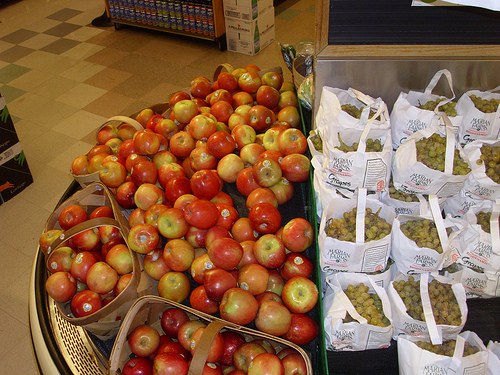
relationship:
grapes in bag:
[324, 207, 391, 243] [324, 193, 398, 257]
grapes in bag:
[348, 285, 376, 324] [322, 272, 395, 342]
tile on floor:
[96, 63, 119, 90] [1, 2, 316, 374]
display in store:
[32, 61, 498, 372] [13, 8, 494, 373]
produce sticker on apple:
[79, 300, 93, 312] [70, 288, 104, 319]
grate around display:
[47, 296, 107, 373] [62, 252, 306, 372]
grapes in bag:
[342, 282, 391, 327] [396, 330, 488, 373]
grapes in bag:
[413, 339, 483, 357] [321, 271, 393, 351]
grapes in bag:
[324, 207, 391, 243] [388, 271, 469, 340]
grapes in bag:
[400, 219, 452, 253] [317, 188, 395, 273]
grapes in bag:
[393, 274, 462, 324] [389, 193, 461, 275]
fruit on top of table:
[254, 156, 282, 188] [27, 175, 117, 372]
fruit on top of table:
[228, 86, 253, 107] [27, 175, 117, 372]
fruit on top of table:
[252, 232, 286, 270] [27, 175, 117, 372]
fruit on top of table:
[124, 221, 159, 252] [27, 175, 117, 372]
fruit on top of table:
[128, 123, 162, 157] [27, 175, 117, 372]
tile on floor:
[1, 0, 315, 374] [1, 2, 316, 374]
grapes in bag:
[425, 141, 442, 168] [328, 282, 390, 347]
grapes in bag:
[407, 220, 434, 244] [466, 204, 498, 244]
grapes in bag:
[331, 210, 385, 237] [395, 337, 498, 370]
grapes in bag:
[338, 142, 378, 152] [322, 81, 389, 137]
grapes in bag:
[410, 94, 454, 109] [393, 67, 460, 140]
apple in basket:
[85, 260, 117, 293] [108, 294, 314, 373]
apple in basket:
[44, 269, 71, 299] [108, 294, 314, 373]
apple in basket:
[128, 324, 157, 353] [40, 184, 157, 339]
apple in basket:
[160, 307, 185, 336] [108, 294, 314, 373]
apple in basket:
[105, 241, 131, 271] [40, 184, 157, 339]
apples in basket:
[66, 113, 162, 183] [69, 110, 146, 194]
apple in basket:
[127, 322, 159, 357] [108, 294, 314, 373]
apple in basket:
[160, 305, 189, 337] [108, 294, 314, 373]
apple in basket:
[188, 324, 221, 362] [108, 294, 314, 373]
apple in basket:
[246, 351, 283, 373] [108, 294, 314, 373]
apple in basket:
[153, 352, 188, 374] [108, 294, 314, 373]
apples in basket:
[0, 53, 321, 373] [92, 223, 143, 299]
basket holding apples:
[108, 294, 314, 373] [123, 309, 303, 374]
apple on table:
[254, 231, 281, 271] [27, 177, 315, 371]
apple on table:
[238, 347, 281, 373] [27, 177, 315, 371]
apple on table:
[155, 267, 202, 307] [27, 177, 315, 371]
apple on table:
[147, 206, 188, 232] [27, 177, 315, 371]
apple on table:
[153, 159, 185, 187] [27, 177, 315, 371]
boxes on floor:
[221, 0, 273, 55] [1, 2, 316, 374]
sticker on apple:
[236, 280, 247, 293] [230, 260, 267, 291]